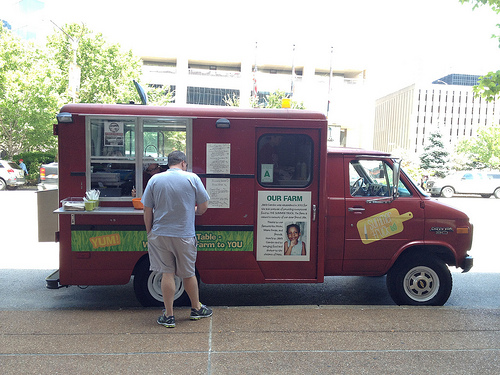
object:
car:
[426, 170, 500, 199]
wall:
[427, 126, 435, 132]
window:
[85, 115, 190, 201]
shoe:
[190, 302, 214, 320]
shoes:
[157, 309, 176, 328]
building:
[372, 73, 500, 172]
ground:
[270, 337, 327, 354]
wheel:
[386, 251, 453, 306]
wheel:
[133, 264, 200, 307]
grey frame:
[85, 114, 193, 202]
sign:
[357, 208, 414, 245]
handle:
[197, 174, 255, 178]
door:
[254, 127, 321, 279]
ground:
[277, 323, 341, 365]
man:
[140, 150, 212, 327]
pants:
[147, 231, 198, 278]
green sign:
[71, 224, 255, 252]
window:
[457, 129, 458, 136]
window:
[432, 90, 434, 102]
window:
[445, 106, 447, 113]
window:
[486, 108, 488, 115]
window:
[416, 127, 418, 134]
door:
[343, 155, 425, 273]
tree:
[0, 20, 55, 160]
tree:
[44, 20, 144, 104]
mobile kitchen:
[45, 103, 474, 308]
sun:
[0, 14, 103, 77]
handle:
[348, 207, 365, 212]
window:
[451, 117, 453, 124]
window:
[419, 89, 421, 100]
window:
[472, 107, 474, 114]